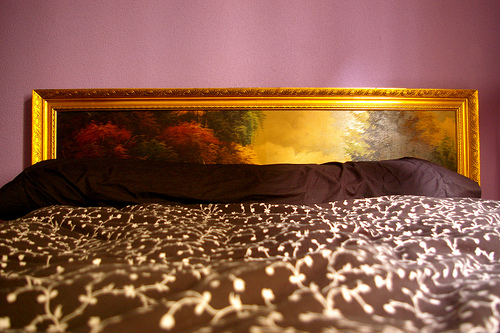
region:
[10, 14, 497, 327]
Large bed in a residence.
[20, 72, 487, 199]
Artistic photo used as a bed headboard.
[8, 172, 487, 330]
Decorative brown and white comforter.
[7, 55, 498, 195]
Purple wall in a bedroom.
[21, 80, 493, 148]
Pretty golden framed artwork.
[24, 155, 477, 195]
Brown pillows on top of bed.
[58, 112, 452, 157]
Multicolored artwork inside a bedroom.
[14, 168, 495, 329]
Queen size bed inside of female's room.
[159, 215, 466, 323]
White floral textile print on a comforter.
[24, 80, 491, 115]
Distinct decorative embossing of an art frame.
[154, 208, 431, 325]
a comforter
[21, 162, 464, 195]
a pillow case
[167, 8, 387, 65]
the wall is purple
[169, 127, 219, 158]
a red bush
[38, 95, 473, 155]
a picture on the wall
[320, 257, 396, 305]
white design on the bed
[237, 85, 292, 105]
frame is gold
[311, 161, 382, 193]
wrinkles in the pillow case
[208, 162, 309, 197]
a black pillow case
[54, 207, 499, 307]
the comforter is black and white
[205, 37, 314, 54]
purple color on wall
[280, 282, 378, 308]
fancy white tree design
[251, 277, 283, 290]
luxurious brown color on sheet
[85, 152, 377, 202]
large brown bed pillow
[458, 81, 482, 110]
edge of large gold picture frame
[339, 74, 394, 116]
light shining on picture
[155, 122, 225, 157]
crimson red tree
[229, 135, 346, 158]
yellow trees spreading its leaves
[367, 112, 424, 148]
tall trees in the air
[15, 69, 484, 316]
large picture behind bed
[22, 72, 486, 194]
A picture frame on a wall.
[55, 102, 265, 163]
a painting of trees on a wall.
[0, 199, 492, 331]
A blanket on a bed.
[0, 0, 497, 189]
a purple wall behind a painting.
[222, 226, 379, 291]
printed blanket on a bed.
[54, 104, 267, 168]
a forest in a painting.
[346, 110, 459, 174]
a lot of trees in a forest.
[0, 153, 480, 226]
the top of a comforter.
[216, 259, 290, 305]
gold print on a blanket.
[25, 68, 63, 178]
a golden picture frame.